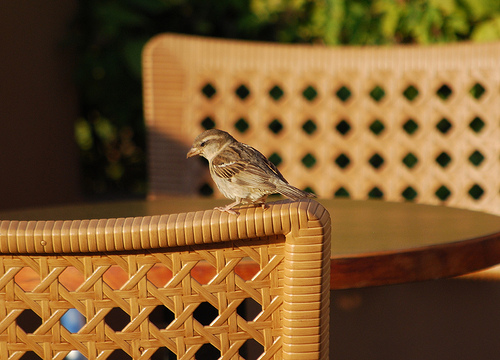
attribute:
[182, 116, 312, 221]
bird — brown, resting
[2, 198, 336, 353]
chair — brown, designed, tan, wicker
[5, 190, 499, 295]
table — round, empty, outdoors, wooden, between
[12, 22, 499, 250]
chairs — patio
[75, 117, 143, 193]
fence — green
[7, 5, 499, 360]
exterior — outdoor, patio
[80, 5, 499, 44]
vegetation — close up, backing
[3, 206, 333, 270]
weave — plastic